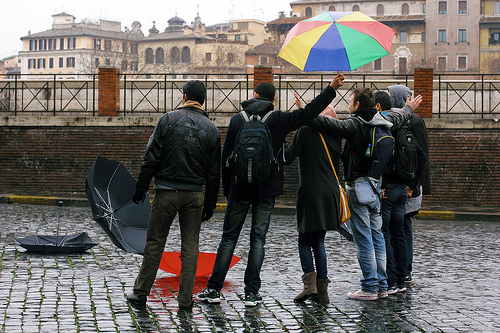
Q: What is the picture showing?
A: It is showing a road.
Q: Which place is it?
A: It is a road.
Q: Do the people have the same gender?
A: No, they are both male and female.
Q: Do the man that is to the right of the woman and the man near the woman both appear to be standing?
A: Yes, both the man and the man are standing.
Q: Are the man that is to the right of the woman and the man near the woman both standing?
A: Yes, both the man and the man are standing.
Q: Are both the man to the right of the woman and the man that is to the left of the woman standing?
A: Yes, both the man and the man are standing.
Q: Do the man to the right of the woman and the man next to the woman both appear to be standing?
A: Yes, both the man and the man are standing.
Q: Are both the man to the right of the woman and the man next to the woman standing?
A: Yes, both the man and the man are standing.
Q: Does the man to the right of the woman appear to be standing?
A: Yes, the man is standing.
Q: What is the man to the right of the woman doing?
A: The man is standing.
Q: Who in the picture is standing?
A: The man is standing.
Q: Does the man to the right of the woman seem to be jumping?
A: No, the man is standing.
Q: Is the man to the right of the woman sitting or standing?
A: The man is standing.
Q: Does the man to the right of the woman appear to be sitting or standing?
A: The man is standing.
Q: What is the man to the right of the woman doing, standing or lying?
A: The man is standing.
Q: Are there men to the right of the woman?
A: Yes, there is a man to the right of the woman.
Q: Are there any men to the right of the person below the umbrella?
A: Yes, there is a man to the right of the woman.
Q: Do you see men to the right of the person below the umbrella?
A: Yes, there is a man to the right of the woman.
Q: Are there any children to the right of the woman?
A: No, there is a man to the right of the woman.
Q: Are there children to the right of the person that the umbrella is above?
A: No, there is a man to the right of the woman.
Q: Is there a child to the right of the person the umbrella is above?
A: No, there is a man to the right of the woman.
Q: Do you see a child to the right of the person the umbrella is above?
A: No, there is a man to the right of the woman.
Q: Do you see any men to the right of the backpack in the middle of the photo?
A: Yes, there is a man to the right of the backpack.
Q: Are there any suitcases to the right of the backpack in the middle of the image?
A: No, there is a man to the right of the backpack.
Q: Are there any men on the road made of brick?
A: Yes, there is a man on the road.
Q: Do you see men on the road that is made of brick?
A: Yes, there is a man on the road.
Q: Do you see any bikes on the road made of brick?
A: No, there is a man on the road.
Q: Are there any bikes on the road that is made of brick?
A: No, there is a man on the road.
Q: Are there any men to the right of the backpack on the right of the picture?
A: Yes, there is a man to the right of the backpack.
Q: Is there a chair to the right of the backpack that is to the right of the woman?
A: No, there is a man to the right of the backpack.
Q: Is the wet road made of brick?
A: Yes, the road is made of brick.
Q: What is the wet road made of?
A: The road is made of brick.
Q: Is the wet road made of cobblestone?
A: No, the road is made of brick.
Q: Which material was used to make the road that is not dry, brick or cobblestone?
A: The road is made of brick.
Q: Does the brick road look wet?
A: Yes, the road is wet.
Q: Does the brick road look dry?
A: No, the road is wet.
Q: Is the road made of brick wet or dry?
A: The road is wet.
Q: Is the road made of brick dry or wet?
A: The road is wet.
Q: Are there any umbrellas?
A: Yes, there is an umbrella.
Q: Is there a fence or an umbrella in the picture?
A: Yes, there is an umbrella.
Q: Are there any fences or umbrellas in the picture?
A: Yes, there is an umbrella.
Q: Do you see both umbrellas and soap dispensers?
A: No, there is an umbrella but no soap dispensers.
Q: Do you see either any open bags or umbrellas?
A: Yes, there is an open umbrella.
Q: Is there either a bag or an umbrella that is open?
A: Yes, the umbrella is open.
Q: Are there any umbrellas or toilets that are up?
A: Yes, the umbrella is up.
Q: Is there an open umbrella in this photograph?
A: Yes, there is an open umbrella.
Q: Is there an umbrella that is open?
A: Yes, there is an umbrella that is open.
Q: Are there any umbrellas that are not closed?
A: Yes, there is a open umbrella.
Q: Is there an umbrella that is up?
A: Yes, there is an umbrella that is up.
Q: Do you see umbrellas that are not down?
A: Yes, there is an umbrella that is up .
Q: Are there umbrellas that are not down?
A: Yes, there is an umbrella that is up.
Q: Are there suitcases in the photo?
A: No, there are no suitcases.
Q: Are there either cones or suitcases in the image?
A: No, there are no suitcases or cones.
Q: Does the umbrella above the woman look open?
A: Yes, the umbrella is open.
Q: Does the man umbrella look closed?
A: No, the umbrella is open.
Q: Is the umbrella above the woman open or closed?
A: The umbrella is open.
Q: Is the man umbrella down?
A: No, the umbrella is up.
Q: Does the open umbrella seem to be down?
A: No, the umbrella is up.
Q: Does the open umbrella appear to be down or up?
A: The umbrella is up.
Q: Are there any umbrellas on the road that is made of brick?
A: Yes, there is an umbrella on the road.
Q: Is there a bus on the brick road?
A: No, there is an umbrella on the road.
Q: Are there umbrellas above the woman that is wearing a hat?
A: Yes, there is an umbrella above the woman.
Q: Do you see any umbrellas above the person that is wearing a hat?
A: Yes, there is an umbrella above the woman.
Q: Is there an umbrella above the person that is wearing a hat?
A: Yes, there is an umbrella above the woman.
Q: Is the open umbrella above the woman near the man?
A: Yes, the umbrella is above the woman.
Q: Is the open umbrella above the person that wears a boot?
A: Yes, the umbrella is above the woman.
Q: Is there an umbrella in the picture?
A: Yes, there is an umbrella.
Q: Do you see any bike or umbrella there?
A: Yes, there is an umbrella.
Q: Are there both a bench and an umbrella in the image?
A: No, there is an umbrella but no benches.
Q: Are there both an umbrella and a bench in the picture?
A: No, there is an umbrella but no benches.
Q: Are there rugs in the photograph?
A: No, there are no rugs.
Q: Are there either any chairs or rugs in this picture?
A: No, there are no rugs or chairs.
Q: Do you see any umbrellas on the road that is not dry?
A: Yes, there is an umbrella on the road.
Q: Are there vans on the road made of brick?
A: No, there is an umbrella on the road.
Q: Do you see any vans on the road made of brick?
A: No, there is an umbrella on the road.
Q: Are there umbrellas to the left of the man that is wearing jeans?
A: Yes, there is an umbrella to the left of the man.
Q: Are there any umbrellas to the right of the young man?
A: No, the umbrella is to the left of the man.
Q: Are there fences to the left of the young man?
A: No, there is an umbrella to the left of the man.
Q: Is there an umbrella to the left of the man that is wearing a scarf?
A: Yes, there is an umbrella to the left of the man.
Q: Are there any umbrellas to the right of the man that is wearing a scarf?
A: No, the umbrella is to the left of the man.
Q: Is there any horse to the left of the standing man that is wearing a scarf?
A: No, there is an umbrella to the left of the man.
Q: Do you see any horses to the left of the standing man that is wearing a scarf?
A: No, there is an umbrella to the left of the man.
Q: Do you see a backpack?
A: Yes, there is a backpack.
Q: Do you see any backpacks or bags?
A: Yes, there is a backpack.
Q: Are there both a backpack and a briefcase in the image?
A: No, there is a backpack but no briefcases.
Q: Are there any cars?
A: No, there are no cars.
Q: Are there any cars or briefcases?
A: No, there are no cars or briefcases.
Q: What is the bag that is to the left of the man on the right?
A: The bag is a backpack.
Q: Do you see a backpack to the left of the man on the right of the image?
A: Yes, there is a backpack to the left of the man.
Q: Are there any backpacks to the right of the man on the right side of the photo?
A: No, the backpack is to the left of the man.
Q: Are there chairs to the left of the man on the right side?
A: No, there is a backpack to the left of the man.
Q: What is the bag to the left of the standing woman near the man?
A: The bag is a backpack.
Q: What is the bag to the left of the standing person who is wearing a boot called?
A: The bag is a backpack.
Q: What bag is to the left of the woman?
A: The bag is a backpack.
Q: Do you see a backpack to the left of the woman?
A: Yes, there is a backpack to the left of the woman.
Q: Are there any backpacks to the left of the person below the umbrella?
A: Yes, there is a backpack to the left of the woman.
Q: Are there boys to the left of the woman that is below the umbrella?
A: No, there is a backpack to the left of the woman.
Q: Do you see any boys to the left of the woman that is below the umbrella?
A: No, there is a backpack to the left of the woman.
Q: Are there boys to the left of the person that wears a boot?
A: No, there is a backpack to the left of the woman.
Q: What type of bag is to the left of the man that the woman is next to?
A: The bag is a backpack.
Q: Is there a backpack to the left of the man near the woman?
A: Yes, there is a backpack to the left of the man.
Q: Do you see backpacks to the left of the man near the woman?
A: Yes, there is a backpack to the left of the man.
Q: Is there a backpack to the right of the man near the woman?
A: No, the backpack is to the left of the man.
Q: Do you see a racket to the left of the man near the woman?
A: No, there is a backpack to the left of the man.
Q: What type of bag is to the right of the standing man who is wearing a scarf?
A: The bag is a backpack.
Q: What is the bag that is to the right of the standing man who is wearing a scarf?
A: The bag is a backpack.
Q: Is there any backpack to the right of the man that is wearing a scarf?
A: Yes, there is a backpack to the right of the man.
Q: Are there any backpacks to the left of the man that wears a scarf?
A: No, the backpack is to the right of the man.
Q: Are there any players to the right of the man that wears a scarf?
A: No, there is a backpack to the right of the man.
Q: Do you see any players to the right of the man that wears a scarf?
A: No, there is a backpack to the right of the man.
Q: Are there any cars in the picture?
A: No, there are no cars.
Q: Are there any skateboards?
A: No, there are no skateboards.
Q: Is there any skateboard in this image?
A: No, there are no skateboards.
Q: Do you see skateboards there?
A: No, there are no skateboards.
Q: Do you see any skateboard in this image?
A: No, there are no skateboards.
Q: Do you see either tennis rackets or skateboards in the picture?
A: No, there are no skateboards or tennis rackets.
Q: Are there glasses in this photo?
A: No, there are no glasses.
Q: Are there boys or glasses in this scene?
A: No, there are no glasses or boys.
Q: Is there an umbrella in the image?
A: Yes, there is an umbrella.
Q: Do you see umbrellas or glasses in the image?
A: Yes, there is an umbrella.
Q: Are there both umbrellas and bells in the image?
A: No, there is an umbrella but no bells.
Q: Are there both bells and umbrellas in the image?
A: No, there is an umbrella but no bells.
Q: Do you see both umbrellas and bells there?
A: No, there is an umbrella but no bells.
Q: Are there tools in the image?
A: No, there are no tools.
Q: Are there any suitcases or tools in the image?
A: No, there are no tools or suitcases.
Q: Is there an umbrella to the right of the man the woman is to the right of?
A: No, the umbrella is to the left of the man.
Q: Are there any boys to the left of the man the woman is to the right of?
A: No, there is an umbrella to the left of the man.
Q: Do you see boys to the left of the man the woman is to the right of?
A: No, there is an umbrella to the left of the man.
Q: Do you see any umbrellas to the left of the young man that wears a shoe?
A: Yes, there is an umbrella to the left of the man.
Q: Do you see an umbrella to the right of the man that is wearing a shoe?
A: No, the umbrella is to the left of the man.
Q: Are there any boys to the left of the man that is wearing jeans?
A: No, there is an umbrella to the left of the man.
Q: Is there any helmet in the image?
A: No, there are no helmets.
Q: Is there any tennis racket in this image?
A: No, there are no rackets.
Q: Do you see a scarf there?
A: Yes, there is a scarf.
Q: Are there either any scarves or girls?
A: Yes, there is a scarf.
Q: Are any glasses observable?
A: No, there are no glasses.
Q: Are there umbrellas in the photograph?
A: Yes, there is an umbrella.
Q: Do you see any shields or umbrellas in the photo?
A: Yes, there is an umbrella.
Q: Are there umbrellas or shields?
A: Yes, there is an umbrella.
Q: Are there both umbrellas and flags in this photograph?
A: No, there is an umbrella but no flags.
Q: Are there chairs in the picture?
A: No, there are no chairs.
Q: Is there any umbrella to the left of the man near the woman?
A: Yes, there is an umbrella to the left of the man.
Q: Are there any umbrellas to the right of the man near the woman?
A: No, the umbrella is to the left of the man.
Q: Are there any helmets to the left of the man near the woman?
A: No, there is an umbrella to the left of the man.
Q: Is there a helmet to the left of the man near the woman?
A: No, there is an umbrella to the left of the man.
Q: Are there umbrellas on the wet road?
A: Yes, there is an umbrella on the road.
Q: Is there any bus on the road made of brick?
A: No, there is an umbrella on the road.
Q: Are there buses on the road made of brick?
A: No, there is an umbrella on the road.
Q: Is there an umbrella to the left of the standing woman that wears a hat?
A: Yes, there is an umbrella to the left of the woman.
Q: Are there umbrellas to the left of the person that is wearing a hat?
A: Yes, there is an umbrella to the left of the woman.